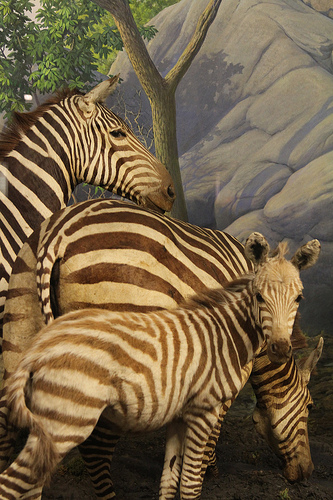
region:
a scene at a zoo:
[6, 7, 326, 498]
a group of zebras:
[2, 69, 332, 499]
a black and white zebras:
[5, 57, 172, 274]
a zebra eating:
[222, 307, 332, 498]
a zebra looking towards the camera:
[2, 229, 332, 499]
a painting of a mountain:
[79, 3, 332, 361]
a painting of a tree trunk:
[78, 0, 234, 237]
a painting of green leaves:
[0, 1, 189, 135]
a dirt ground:
[2, 260, 332, 490]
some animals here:
[5, 2, 331, 495]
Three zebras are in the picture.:
[6, 74, 327, 499]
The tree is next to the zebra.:
[1, 4, 139, 162]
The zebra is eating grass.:
[264, 427, 322, 498]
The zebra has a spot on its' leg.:
[167, 449, 181, 474]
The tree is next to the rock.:
[114, 0, 290, 99]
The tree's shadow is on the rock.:
[171, 57, 239, 130]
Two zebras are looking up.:
[89, 80, 303, 332]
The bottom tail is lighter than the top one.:
[5, 273, 96, 384]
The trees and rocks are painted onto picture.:
[2, 0, 242, 77]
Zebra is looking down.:
[263, 370, 322, 424]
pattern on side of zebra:
[110, 225, 187, 288]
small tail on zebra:
[6, 354, 60, 477]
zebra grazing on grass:
[254, 336, 324, 480]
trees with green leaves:
[0, 1, 92, 80]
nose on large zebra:
[149, 176, 181, 211]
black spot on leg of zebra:
[159, 449, 179, 477]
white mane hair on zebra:
[269, 234, 287, 263]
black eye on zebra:
[101, 119, 136, 154]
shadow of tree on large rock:
[170, 41, 251, 148]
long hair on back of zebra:
[0, 96, 58, 164]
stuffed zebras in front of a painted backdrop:
[1, 60, 330, 497]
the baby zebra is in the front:
[3, 230, 323, 496]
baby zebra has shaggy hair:
[3, 230, 325, 498]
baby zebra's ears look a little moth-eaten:
[237, 224, 323, 369]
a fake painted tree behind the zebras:
[0, 1, 223, 223]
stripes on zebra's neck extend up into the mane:
[171, 268, 261, 314]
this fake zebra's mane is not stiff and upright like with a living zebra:
[176, 258, 257, 316]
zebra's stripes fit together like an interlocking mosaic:
[102, 309, 190, 395]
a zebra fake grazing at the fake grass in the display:
[252, 326, 327, 499]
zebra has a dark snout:
[141, 150, 180, 219]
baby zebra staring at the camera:
[2, 230, 317, 497]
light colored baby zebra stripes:
[55, 324, 173, 413]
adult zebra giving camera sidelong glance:
[25, 70, 171, 215]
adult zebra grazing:
[2, 195, 322, 495]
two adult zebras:
[0, 76, 323, 481]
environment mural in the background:
[0, 0, 329, 225]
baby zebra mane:
[173, 271, 253, 312]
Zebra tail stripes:
[34, 233, 61, 325]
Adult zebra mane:
[0, 86, 83, 162]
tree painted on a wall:
[120, 39, 208, 220]